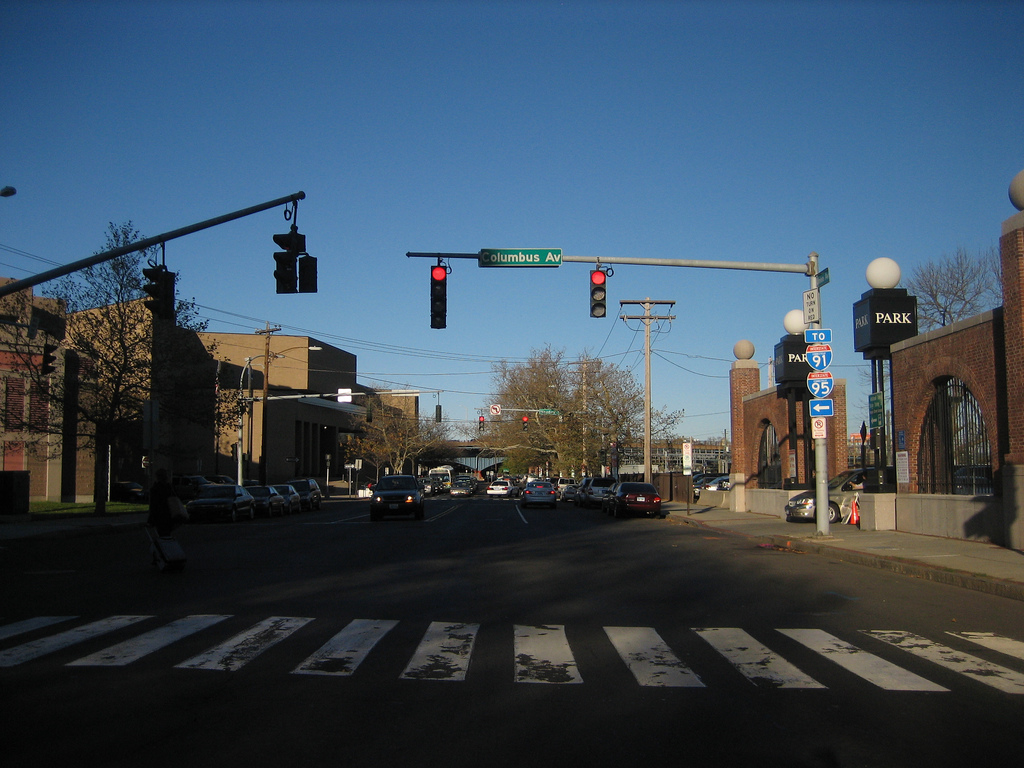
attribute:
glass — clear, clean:
[874, 385, 1013, 513]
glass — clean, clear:
[866, 363, 1018, 536]